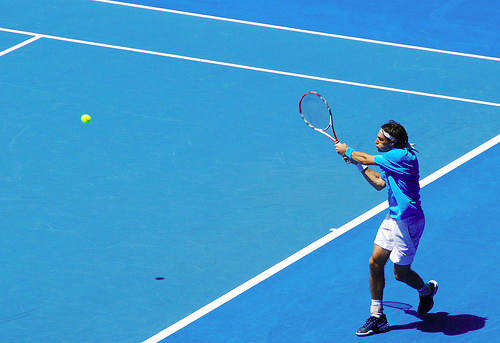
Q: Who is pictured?
A: A man.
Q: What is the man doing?
A: Playing tennis.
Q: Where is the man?
A: Tennis court.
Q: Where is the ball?
A: In the air.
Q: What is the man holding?
A: Tennis racket.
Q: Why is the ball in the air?
A: The man hit it there.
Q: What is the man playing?
A: Tennis.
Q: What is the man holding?
A: Tennis racket.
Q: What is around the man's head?
A: Bandana.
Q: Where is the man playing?
A: On tennis court.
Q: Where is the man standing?
A: Behind white line.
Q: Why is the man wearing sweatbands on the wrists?
A: To wipe his face with.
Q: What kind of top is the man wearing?
A: Blue polo shirt.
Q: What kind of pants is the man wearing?
A: White shorts.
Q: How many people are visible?
A: One.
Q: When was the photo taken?
A: Daytime.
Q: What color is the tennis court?
A: Blue.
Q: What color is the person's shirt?
A: Blue.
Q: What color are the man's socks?
A: White.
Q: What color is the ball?
A: Yellow.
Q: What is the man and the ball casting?
A: A shadow.